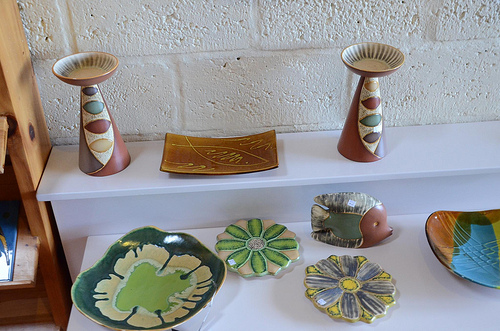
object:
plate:
[421, 200, 499, 288]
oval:
[86, 137, 115, 152]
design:
[360, 112, 383, 126]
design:
[82, 100, 102, 113]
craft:
[306, 191, 392, 247]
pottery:
[302, 251, 398, 326]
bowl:
[71, 225, 226, 330]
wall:
[17, 1, 498, 146]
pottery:
[211, 217, 301, 279]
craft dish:
[157, 130, 277, 174]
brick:
[168, 51, 356, 137]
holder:
[333, 42, 405, 162]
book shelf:
[0, 209, 40, 290]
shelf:
[33, 119, 499, 198]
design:
[362, 131, 382, 144]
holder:
[50, 47, 132, 179]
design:
[85, 136, 113, 151]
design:
[362, 76, 380, 94]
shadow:
[164, 262, 245, 330]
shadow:
[264, 258, 344, 330]